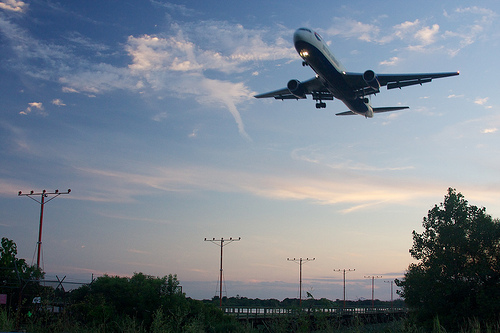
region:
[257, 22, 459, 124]
airplane flying in the sky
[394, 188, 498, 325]
big green foliage of a tree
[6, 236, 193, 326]
twoo green bushes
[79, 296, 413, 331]
large fence cover with bushes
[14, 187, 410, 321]
bunch of red large poles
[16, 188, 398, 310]
electricity poles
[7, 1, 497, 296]
clue cloudy sky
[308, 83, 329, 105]
small black aircraft engine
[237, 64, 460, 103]
two wings of an airplane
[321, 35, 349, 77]
bunch of windows in the airplane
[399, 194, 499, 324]
green tree in the right side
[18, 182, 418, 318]
six Electricity pylons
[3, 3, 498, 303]
blue and cloudy sky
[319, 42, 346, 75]
bunch of windows in the airplane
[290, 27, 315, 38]
pilothouse in the airplane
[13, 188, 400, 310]
large red poles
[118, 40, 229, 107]
The clouds are sparse.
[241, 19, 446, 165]
The plane is in the air.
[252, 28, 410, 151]
The plane is flying.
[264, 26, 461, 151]
The plane is white.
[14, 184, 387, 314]
The telephone poles are tall.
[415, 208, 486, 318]
The tree is leafy.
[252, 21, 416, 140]
The plane is large.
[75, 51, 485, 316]
The sun is rising.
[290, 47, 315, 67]
The light is on.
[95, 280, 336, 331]
The train is on the track.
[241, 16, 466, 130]
plane is flying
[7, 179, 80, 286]
t-shaped tall utility pole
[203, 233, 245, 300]
t-shaped tall utility pole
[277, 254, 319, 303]
t-shaped tall utility pole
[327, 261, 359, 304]
t-shaped tall utility pole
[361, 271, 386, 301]
t-shaped tall utility pole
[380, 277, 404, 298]
t-shaped tall utility pole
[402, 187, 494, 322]
tall tree with leaves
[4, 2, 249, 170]
sky is partially cloudy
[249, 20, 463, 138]
plane with headlight on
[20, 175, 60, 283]
power line along river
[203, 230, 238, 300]
power line along river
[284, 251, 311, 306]
power line along river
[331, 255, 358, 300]
power line along river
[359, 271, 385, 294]
power line along river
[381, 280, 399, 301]
power line along river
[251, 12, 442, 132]
plane flying in sky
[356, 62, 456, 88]
wing on side of plane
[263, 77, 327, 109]
wing on side of plane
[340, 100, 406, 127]
tail wing on plane